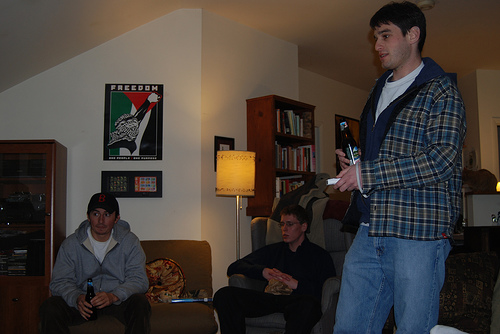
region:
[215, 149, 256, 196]
the lamp is turned on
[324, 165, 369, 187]
a white Wii remote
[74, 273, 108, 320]
a beer in the guys hand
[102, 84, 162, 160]
a poster on the wall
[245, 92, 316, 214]
a shelf full of books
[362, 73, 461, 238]
a blue plaid jacket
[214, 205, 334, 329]
a young man sitting in the chair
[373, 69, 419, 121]
a white under shirt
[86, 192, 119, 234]
guy is wearing a baseball hat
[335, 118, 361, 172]
man is holding a beer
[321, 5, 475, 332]
man standing in the room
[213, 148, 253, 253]
floor lamp by the chair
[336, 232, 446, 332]
blue jeans man is wearing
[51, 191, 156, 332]
man sitting in a chair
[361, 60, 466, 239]
jacket man is wearing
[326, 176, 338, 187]
remote control in man's hand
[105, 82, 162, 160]
picture hanging on the wall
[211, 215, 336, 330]
brown chair young man is sitting in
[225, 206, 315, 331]
young man sitting in the brown chair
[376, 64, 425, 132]
white tee shirt young man is wearing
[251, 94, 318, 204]
Books on a hanging shelf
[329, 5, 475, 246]
Boy wearing blue plaid jacket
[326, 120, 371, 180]
Boy holding dark glass bottle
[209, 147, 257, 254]
Yellow lamp shade on a tall lamp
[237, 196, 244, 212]
Silver pull chain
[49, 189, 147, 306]
Boy wearing gray jacket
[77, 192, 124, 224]
Back cap with red letter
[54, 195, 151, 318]
Boy sitting hold dark glass bottle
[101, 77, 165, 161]
Black, green, red and white picture on wall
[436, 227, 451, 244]
Red tag on blue plaid jacket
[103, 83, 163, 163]
black, white, red, and green poster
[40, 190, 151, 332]
man in gray shirt and black hat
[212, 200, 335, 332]
man in glasses wearing all black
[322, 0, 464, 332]
man in plaid jacket and blue jeans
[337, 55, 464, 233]
blue and black plaid jacket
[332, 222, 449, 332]
light blue denim jeans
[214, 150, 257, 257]
metal lamp with yellow shade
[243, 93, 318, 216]
brown wooden shelf with assorted books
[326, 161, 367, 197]
hand with white wii remote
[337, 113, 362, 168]
bottle of beer with blue label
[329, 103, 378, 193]
this is a bottle of beer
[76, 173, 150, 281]
he is wearing a baseball cap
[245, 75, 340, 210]
this is a bookcase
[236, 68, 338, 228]
a book shelf against the wall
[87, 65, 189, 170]
this is a poster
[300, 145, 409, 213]
he is holding a Nintendo controller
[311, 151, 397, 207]
he is holding a Nintendo Wii controller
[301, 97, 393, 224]
he has a beer in one hand and a controller in the other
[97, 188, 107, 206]
a red letter "B" on his cap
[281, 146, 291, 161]
a book on the shelf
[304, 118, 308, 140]
a book on the shelf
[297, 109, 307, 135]
a book on the shelf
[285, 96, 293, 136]
a book on the shelf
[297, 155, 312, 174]
a book on the shelf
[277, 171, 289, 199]
a book on the shelf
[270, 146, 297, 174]
a book on the shelf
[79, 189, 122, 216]
ball cap covering man's head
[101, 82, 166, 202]
art decor affixed to wall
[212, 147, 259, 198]
lamp shade on pole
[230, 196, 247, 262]
pole portion of lamp